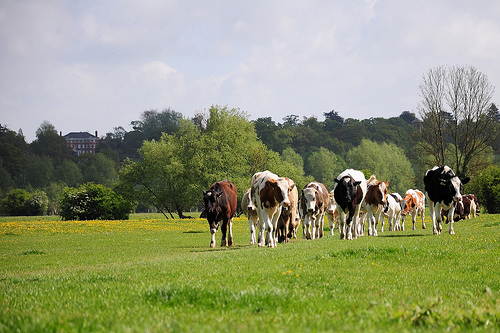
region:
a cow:
[136, 146, 251, 272]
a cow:
[174, 177, 261, 317]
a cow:
[151, 133, 295, 318]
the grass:
[251, 282, 319, 329]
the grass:
[331, 256, 373, 284]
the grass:
[291, 233, 348, 308]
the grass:
[254, 209, 336, 331]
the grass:
[266, 257, 331, 325]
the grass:
[267, 223, 379, 327]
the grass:
[326, 261, 396, 321]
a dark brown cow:
[201, 176, 236, 247]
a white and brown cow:
[248, 169, 292, 247]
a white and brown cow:
[237, 189, 262, 246]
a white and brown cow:
[301, 177, 329, 240]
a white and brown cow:
[278, 176, 300, 241]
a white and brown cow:
[364, 177, 386, 234]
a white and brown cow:
[400, 186, 426, 228]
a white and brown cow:
[442, 189, 480, 222]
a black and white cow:
[420, 162, 464, 234]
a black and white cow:
[333, 170, 365, 240]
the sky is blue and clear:
[58, 39, 201, 104]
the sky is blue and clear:
[51, 6, 130, 84]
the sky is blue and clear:
[44, 16, 116, 66]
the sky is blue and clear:
[84, 54, 180, 151]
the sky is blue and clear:
[84, 95, 266, 272]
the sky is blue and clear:
[112, 78, 202, 97]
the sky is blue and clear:
[93, 40, 158, 99]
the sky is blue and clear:
[32, 9, 158, 146]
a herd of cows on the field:
[199, 163, 477, 249]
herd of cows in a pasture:
[200, 163, 480, 248]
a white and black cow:
[332, 168, 367, 237]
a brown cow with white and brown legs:
[200, 180, 236, 246]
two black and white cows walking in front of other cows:
[333, 165, 470, 240]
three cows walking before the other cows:
[248, 165, 470, 248]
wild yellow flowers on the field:
[0, 217, 188, 237]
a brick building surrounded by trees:
[32, 118, 127, 179]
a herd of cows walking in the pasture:
[0, 157, 497, 331]